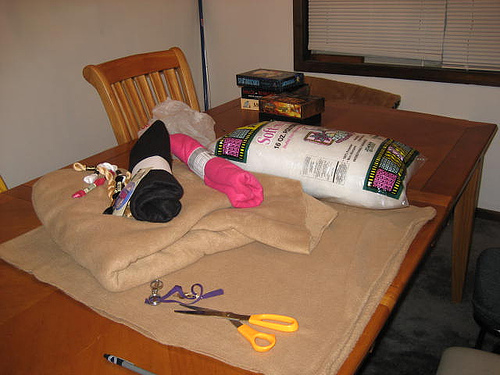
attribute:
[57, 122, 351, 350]
fleece — brown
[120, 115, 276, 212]
fabric — fleece, black, pink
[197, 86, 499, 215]
table — wooden, brown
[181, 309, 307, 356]
scissors — yellow